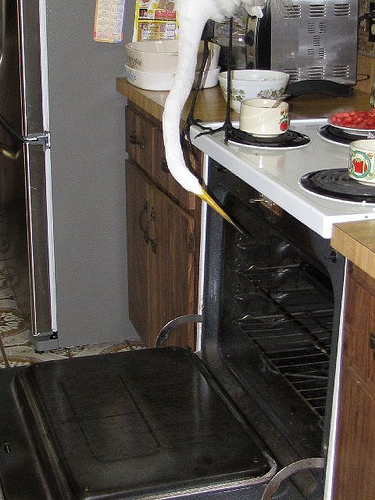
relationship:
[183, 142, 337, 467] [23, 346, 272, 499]
oven has door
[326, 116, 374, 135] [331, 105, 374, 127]
plate has red food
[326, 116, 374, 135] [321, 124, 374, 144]
plate on burner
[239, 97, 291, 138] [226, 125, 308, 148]
bowl on burner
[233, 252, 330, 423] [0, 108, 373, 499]
grate in oven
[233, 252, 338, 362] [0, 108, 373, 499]
grate in oven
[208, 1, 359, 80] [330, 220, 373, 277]
toaster on countertop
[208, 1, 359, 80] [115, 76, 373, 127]
toaster on countertop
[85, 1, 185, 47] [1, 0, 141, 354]
stickers on fridge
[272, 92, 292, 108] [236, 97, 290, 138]
utensil in bowl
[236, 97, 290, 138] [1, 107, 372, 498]
bowl on stove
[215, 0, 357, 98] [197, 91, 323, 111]
oven on counter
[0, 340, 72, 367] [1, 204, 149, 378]
tile of floor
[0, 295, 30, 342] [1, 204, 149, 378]
tile of floor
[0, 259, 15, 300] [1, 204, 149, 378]
tile of floor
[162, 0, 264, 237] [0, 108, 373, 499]
bird looking in oven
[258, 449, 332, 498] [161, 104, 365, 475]
hinge on side of oven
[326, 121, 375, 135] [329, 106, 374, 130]
plate with red food